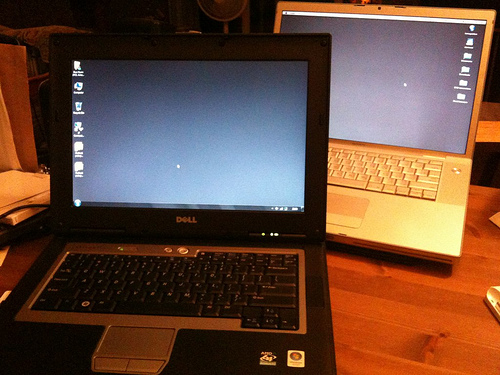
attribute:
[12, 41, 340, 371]
computer — black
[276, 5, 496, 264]
laptop — silver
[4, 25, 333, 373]
laptop — black, Dell's, open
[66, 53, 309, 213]
screen — open, of desktop, of Laptop, active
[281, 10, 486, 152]
screen — open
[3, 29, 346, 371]
black laptop — Dell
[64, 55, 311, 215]
monitor — illuminated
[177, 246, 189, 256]
button — power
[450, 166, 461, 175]
button — power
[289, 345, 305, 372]
tag — Windows, Microsoft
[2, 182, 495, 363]
table — brown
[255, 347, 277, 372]
sticker — black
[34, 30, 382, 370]
laptop — black, computer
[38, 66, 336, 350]
laptop — Dell's, black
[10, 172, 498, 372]
desk — wooden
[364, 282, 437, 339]
desk — wooden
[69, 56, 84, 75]
icon — six, a program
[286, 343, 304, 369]
sticker — Windows'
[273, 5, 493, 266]
computer — silver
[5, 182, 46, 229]
disk — black, white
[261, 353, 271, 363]
writing — white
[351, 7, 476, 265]
laptop — silver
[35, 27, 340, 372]
laptop — black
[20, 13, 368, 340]
laptop — black